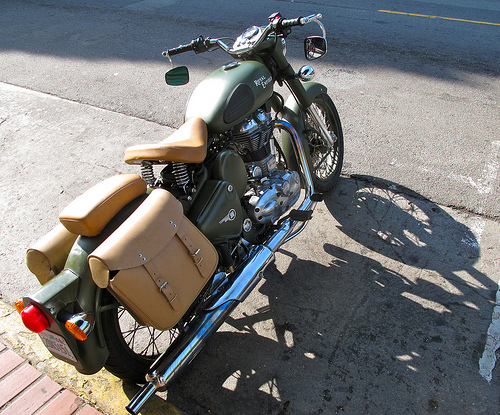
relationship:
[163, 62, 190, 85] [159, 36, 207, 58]
mirror attached to handlebar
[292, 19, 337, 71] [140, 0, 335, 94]
mirror attached to handlebar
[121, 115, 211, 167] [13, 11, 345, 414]
seat attached to motorbike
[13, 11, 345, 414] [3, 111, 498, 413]
motorbike in parking spot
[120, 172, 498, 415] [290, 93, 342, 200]
shadow of tire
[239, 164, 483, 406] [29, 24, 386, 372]
shadow being cast by motorcycle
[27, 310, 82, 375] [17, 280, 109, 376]
license plate on back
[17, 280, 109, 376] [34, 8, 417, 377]
back of motorcycle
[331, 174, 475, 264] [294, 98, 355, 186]
reflection of wheel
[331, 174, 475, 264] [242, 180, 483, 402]
reflection on sidewalk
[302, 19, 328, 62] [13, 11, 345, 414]
mirror on motorbike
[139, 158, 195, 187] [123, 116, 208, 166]
springs on motorbike seat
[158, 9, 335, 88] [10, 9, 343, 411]
handlebars of motorbike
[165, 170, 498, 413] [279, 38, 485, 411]
shadow on ground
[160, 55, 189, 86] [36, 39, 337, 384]
mirror on motorcycle